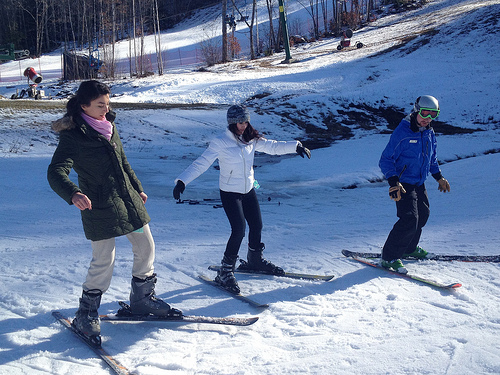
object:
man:
[377, 95, 442, 274]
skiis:
[337, 251, 498, 291]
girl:
[172, 102, 309, 256]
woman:
[45, 77, 157, 312]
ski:
[95, 302, 260, 329]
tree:
[29, 8, 162, 77]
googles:
[414, 106, 439, 120]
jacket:
[376, 116, 438, 184]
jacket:
[175, 130, 300, 193]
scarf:
[83, 113, 114, 144]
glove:
[298, 144, 311, 160]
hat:
[224, 103, 250, 124]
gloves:
[433, 179, 451, 194]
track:
[0, 201, 496, 373]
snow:
[0, 96, 499, 372]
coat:
[45, 110, 150, 238]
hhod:
[404, 107, 423, 122]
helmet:
[411, 95, 443, 120]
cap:
[226, 105, 250, 125]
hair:
[233, 124, 263, 139]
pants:
[219, 185, 263, 262]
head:
[62, 80, 118, 114]